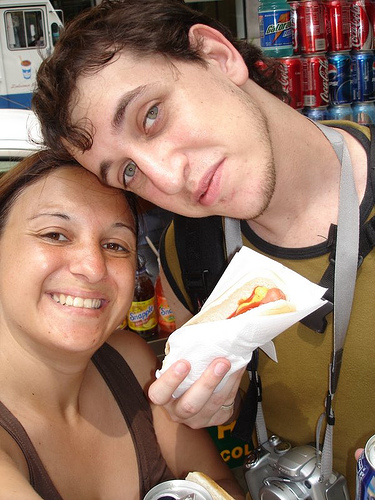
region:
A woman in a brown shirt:
[4, 151, 187, 498]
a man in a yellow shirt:
[74, 31, 374, 492]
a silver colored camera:
[242, 415, 350, 498]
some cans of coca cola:
[261, 5, 370, 105]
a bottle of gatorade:
[259, 0, 302, 58]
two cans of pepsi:
[327, 54, 374, 104]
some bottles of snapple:
[121, 242, 193, 329]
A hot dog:
[164, 275, 292, 373]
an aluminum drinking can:
[140, 477, 210, 498]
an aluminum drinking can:
[354, 434, 373, 498]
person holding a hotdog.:
[148, 274, 304, 425]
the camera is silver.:
[245, 429, 352, 498]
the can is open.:
[140, 477, 210, 498]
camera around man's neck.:
[234, 119, 358, 498]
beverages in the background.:
[237, 3, 370, 123]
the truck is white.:
[1, 0, 69, 89]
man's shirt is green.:
[160, 207, 373, 460]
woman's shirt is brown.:
[5, 343, 168, 498]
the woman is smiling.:
[41, 282, 109, 320]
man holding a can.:
[351, 432, 373, 497]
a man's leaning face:
[28, 19, 275, 219]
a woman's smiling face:
[5, 162, 133, 357]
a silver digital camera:
[246, 436, 345, 498]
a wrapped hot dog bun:
[168, 244, 309, 385]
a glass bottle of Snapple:
[127, 266, 157, 335]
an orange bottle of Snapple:
[152, 263, 177, 335]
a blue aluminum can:
[352, 434, 373, 498]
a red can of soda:
[294, 1, 325, 55]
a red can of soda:
[326, 0, 351, 49]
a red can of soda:
[296, 53, 328, 109]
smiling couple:
[11, 87, 285, 344]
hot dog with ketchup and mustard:
[186, 276, 306, 380]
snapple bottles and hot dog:
[118, 278, 304, 373]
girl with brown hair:
[3, 160, 155, 361]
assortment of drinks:
[244, 5, 373, 113]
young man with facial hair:
[29, 19, 346, 212]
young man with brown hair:
[31, 24, 313, 207]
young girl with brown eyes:
[3, 157, 146, 393]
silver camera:
[235, 405, 352, 497]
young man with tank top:
[40, 22, 369, 275]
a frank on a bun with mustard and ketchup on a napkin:
[211, 269, 304, 325]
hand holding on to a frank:
[144, 350, 248, 434]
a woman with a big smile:
[23, 273, 126, 326]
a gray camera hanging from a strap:
[244, 365, 353, 498]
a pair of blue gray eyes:
[117, 88, 163, 194]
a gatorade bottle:
[256, 3, 295, 58]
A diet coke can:
[345, 0, 371, 51]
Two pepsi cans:
[325, 50, 374, 105]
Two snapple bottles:
[121, 258, 177, 338]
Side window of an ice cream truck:
[0, 5, 58, 92]